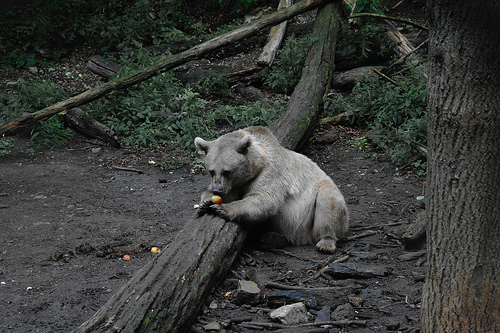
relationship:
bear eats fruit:
[179, 110, 340, 259] [205, 189, 225, 206]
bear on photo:
[179, 110, 340, 259] [7, 5, 493, 330]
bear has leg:
[179, 110, 340, 259] [308, 179, 346, 257]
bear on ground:
[179, 110, 340, 259] [0, 0, 427, 332]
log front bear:
[63, 212, 250, 326] [179, 110, 340, 259]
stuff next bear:
[233, 274, 321, 320] [179, 110, 340, 259]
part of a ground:
[359, 211, 402, 261] [10, 172, 174, 267]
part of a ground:
[359, 211, 402, 261] [345, 252, 422, 309]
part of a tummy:
[359, 211, 402, 261] [275, 191, 316, 245]